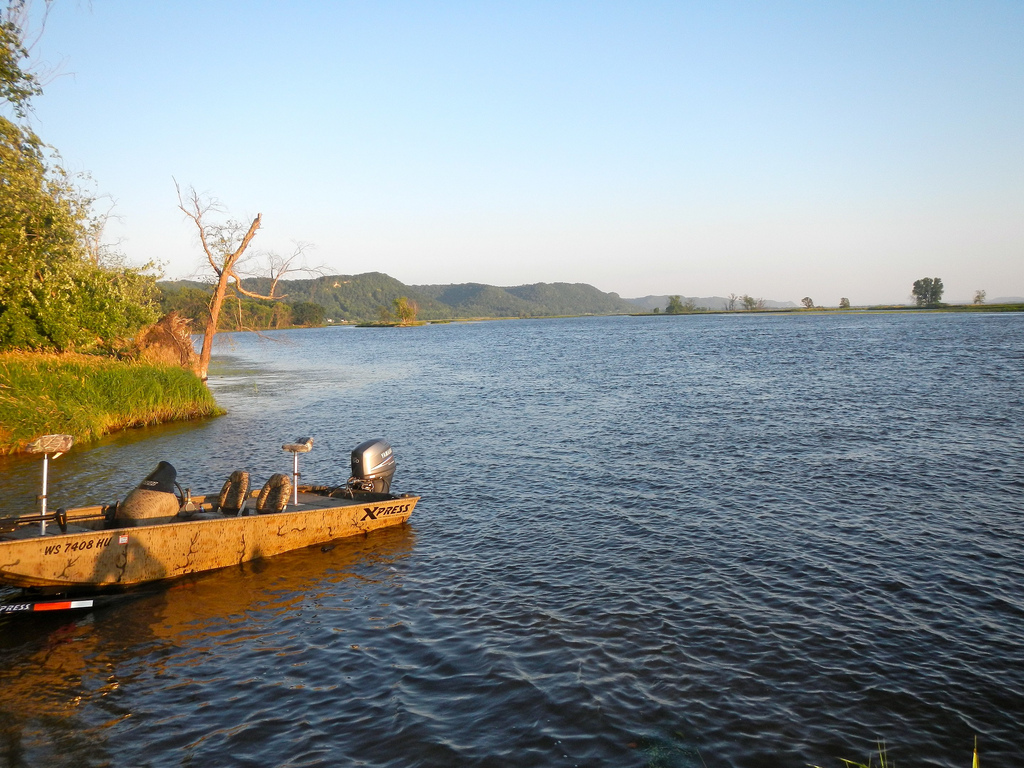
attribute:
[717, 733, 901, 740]
van — white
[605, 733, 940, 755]
van — white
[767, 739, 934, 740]
van — white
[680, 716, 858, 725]
van — white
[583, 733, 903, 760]
van — white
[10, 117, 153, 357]
bush — green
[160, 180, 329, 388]
tree — without leaves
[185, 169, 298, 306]
branches — tree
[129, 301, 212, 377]
trunk — tree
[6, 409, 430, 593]
boat — water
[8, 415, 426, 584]
speedboat — engine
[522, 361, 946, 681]
body — water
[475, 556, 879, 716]
ripples — water, small 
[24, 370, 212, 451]
shore line — water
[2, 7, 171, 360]
tree — dead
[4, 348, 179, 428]
grasses — green 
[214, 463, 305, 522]
seats — boat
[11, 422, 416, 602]
boat — serial number, seats 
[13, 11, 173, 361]
trees — section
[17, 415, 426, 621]
boat — black engine 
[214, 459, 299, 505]
boat — two seats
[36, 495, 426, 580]
boat — black writing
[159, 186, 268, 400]
tree — shore line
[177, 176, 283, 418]
tree — shore line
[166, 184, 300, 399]
tree — shore line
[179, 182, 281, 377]
tree — shore line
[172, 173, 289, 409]
tree — shore line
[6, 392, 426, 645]
boat — motor 